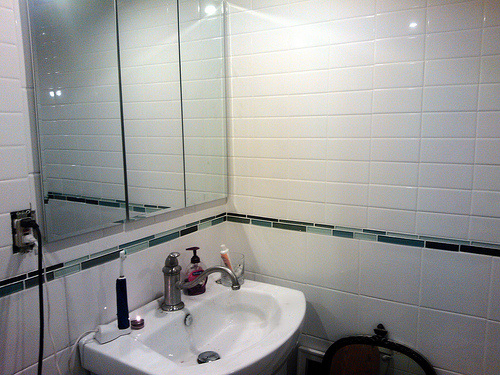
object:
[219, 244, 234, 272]
tube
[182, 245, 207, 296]
bottle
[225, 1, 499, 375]
wall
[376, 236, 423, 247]
green tile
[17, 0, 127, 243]
mirror cabinet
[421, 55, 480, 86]
tiles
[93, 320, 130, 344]
base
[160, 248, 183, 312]
sink drain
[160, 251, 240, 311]
faucet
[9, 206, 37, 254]
outlet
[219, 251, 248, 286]
drinking glass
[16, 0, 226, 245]
mirror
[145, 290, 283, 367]
sink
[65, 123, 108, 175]
glass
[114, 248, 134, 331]
toothbrush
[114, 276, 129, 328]
handle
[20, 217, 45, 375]
cord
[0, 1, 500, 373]
bathroom